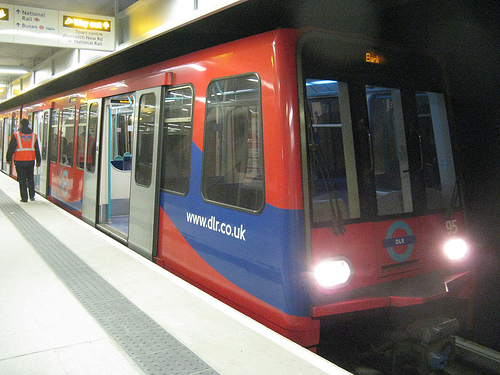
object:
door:
[95, 86, 165, 261]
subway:
[0, 25, 497, 352]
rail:
[322, 320, 499, 375]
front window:
[298, 73, 463, 227]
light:
[309, 237, 469, 287]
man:
[5, 118, 41, 202]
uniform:
[3, 127, 40, 199]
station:
[0, 0, 499, 373]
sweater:
[6, 127, 43, 167]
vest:
[13, 130, 37, 161]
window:
[202, 71, 266, 215]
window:
[161, 83, 195, 198]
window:
[85, 102, 98, 173]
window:
[58, 106, 74, 168]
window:
[47, 110, 60, 164]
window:
[135, 92, 155, 188]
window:
[32, 109, 50, 161]